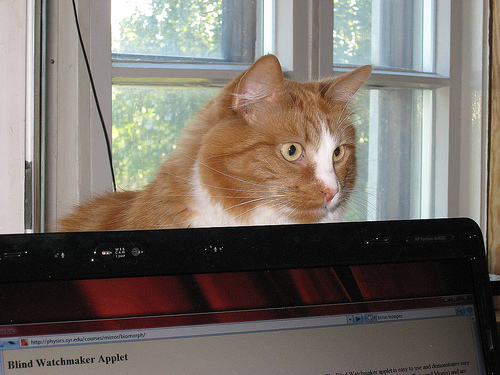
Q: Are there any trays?
A: No, there are no trays.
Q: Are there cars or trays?
A: No, there are no trays or cars.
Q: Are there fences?
A: No, there are no fences.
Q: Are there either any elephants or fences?
A: No, there are no fences or elephants.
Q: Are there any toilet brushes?
A: No, there are no toilet brushes.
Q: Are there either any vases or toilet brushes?
A: No, there are no toilet brushes or vases.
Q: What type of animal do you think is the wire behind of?
A: The wire is behind the cat.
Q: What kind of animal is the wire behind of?
A: The wire is behind the cat.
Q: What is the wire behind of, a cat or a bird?
A: The wire is behind a cat.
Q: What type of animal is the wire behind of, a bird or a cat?
A: The wire is behind a cat.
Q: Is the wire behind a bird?
A: No, the wire is behind the cat.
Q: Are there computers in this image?
A: Yes, there is a computer.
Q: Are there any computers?
A: Yes, there is a computer.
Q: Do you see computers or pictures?
A: Yes, there is a computer.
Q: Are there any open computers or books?
A: Yes, there is an open computer.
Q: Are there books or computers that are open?
A: Yes, the computer is open.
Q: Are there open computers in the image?
A: Yes, there is an open computer.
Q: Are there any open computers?
A: Yes, there is an open computer.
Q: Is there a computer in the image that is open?
A: Yes, there is a computer that is open.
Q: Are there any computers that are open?
A: Yes, there is a computer that is open.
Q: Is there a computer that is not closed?
A: Yes, there is a open computer.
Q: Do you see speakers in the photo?
A: No, there are no speakers.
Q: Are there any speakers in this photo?
A: No, there are no speakers.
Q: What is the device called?
A: The device is a computer.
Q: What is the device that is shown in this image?
A: The device is a computer.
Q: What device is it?
A: The device is a computer.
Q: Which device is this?
A: This is a computer.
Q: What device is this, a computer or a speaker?
A: This is a computer.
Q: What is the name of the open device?
A: The device is a computer.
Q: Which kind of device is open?
A: The device is a computer.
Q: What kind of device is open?
A: The device is a computer.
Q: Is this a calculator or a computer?
A: This is a computer.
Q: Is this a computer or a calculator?
A: This is a computer.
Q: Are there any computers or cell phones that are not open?
A: No, there is a computer but it is open.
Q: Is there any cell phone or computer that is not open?
A: No, there is a computer but it is open.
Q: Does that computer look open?
A: Yes, the computer is open.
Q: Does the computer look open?
A: Yes, the computer is open.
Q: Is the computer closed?
A: No, the computer is open.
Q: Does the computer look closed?
A: No, the computer is open.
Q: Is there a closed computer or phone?
A: No, there is a computer but it is open.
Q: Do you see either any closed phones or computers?
A: No, there is a computer but it is open.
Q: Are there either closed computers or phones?
A: No, there is a computer but it is open.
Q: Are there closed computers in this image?
A: No, there is a computer but it is open.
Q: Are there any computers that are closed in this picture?
A: No, there is a computer but it is open.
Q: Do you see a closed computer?
A: No, there is a computer but it is open.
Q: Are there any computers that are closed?
A: No, there is a computer but it is open.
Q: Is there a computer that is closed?
A: No, there is a computer but it is open.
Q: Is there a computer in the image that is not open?
A: No, there is a computer but it is open.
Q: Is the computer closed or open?
A: The computer is open.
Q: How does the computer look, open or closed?
A: The computer is open.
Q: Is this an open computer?
A: Yes, this is an open computer.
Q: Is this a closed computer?
A: No, this is an open computer.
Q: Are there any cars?
A: No, there are no cars.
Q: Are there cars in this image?
A: No, there are no cars.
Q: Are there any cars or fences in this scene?
A: No, there are no cars or fences.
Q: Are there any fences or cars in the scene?
A: No, there are no cars or fences.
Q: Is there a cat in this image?
A: Yes, there is a cat.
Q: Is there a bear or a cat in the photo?
A: Yes, there is a cat.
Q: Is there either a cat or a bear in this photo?
A: Yes, there is a cat.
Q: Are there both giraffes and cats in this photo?
A: No, there is a cat but no giraffes.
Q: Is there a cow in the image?
A: No, there are no cows.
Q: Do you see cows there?
A: No, there are no cows.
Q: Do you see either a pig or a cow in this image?
A: No, there are no cows or pigs.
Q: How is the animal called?
A: The animal is a cat.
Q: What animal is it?
A: The animal is a cat.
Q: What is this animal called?
A: This is a cat.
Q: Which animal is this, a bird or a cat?
A: This is a cat.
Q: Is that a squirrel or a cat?
A: That is a cat.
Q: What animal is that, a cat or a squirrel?
A: That is a cat.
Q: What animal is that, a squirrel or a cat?
A: That is a cat.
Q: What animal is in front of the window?
A: The cat is in front of the window.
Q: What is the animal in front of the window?
A: The animal is a cat.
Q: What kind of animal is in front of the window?
A: The animal is a cat.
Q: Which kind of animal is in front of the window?
A: The animal is a cat.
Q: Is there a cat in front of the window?
A: Yes, there is a cat in front of the window.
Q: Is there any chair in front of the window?
A: No, there is a cat in front of the window.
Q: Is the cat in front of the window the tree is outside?
A: Yes, the cat is in front of the window.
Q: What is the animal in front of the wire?
A: The animal is a cat.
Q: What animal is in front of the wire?
A: The animal is a cat.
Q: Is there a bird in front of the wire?
A: No, there is a cat in front of the wire.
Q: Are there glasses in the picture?
A: No, there are no glasses.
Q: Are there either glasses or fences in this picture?
A: No, there are no glasses or fences.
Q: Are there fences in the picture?
A: No, there are no fences.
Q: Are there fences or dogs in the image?
A: No, there are no fences or dogs.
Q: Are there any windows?
A: Yes, there is a window.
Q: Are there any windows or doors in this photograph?
A: Yes, there is a window.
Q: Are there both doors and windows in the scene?
A: No, there is a window but no doors.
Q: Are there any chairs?
A: No, there are no chairs.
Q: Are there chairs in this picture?
A: No, there are no chairs.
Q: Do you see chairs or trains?
A: No, there are no chairs or trains.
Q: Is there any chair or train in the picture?
A: No, there are no chairs or trains.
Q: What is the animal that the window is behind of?
A: The animal is a cat.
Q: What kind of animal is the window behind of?
A: The window is behind the cat.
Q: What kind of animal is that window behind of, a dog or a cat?
A: The window is behind a cat.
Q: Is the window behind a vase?
A: No, the window is behind the cat.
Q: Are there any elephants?
A: No, there are no elephants.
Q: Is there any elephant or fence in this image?
A: No, there are no elephants or fences.